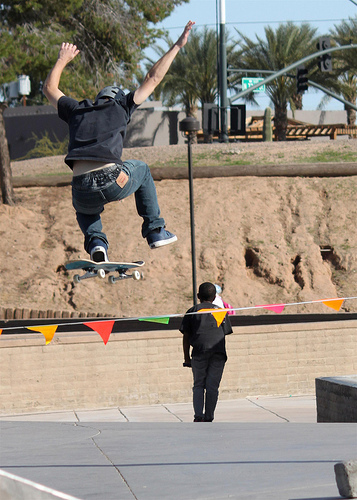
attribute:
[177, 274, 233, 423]
boy — walking away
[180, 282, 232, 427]
boy — standing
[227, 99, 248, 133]
light — black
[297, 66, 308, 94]
light — black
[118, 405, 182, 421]
square — white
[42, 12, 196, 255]
skateboarder — performing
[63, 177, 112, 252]
jeans — blue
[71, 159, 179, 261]
jeans — blue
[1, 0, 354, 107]
sky — blue, clear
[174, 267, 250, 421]
kid — small, black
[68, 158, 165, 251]
pants — blue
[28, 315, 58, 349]
flag — small, yellow, triangular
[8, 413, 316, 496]
concrete — white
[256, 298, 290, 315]
flag — small, triangular, pink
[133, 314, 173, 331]
flag — small, plastic, triangle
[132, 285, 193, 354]
green flag — triangular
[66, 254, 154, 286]
skateboard — wooden, Long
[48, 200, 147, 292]
skateboard — in air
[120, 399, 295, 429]
concrete — white 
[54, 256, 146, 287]
board — flying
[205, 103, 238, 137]
street light — black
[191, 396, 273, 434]
pad — concrete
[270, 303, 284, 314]
flag — triangle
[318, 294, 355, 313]
orange flag — small, triangular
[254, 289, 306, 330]
flag — triangle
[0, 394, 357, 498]
concrete — white, dark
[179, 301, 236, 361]
black shirt — small, short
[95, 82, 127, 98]
helmet — grey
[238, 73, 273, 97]
street sign — green